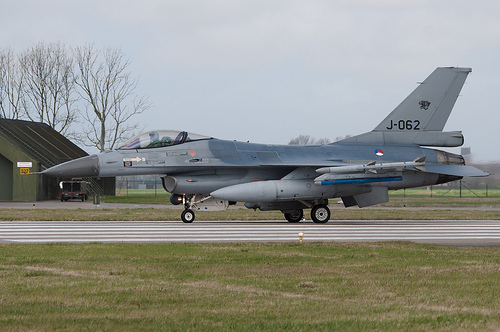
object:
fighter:
[28, 66, 491, 221]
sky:
[2, 4, 494, 176]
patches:
[3, 240, 494, 325]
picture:
[1, 0, 498, 327]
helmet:
[147, 131, 160, 142]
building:
[0, 119, 116, 202]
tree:
[3, 62, 25, 113]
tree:
[41, 46, 67, 122]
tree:
[79, 53, 111, 139]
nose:
[35, 161, 97, 178]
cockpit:
[126, 126, 197, 148]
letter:
[387, 119, 394, 130]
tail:
[375, 63, 472, 150]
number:
[398, 119, 406, 131]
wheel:
[310, 204, 331, 223]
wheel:
[179, 209, 199, 224]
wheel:
[284, 208, 304, 223]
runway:
[2, 221, 495, 238]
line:
[62, 227, 71, 229]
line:
[124, 232, 139, 237]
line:
[163, 228, 169, 229]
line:
[104, 219, 108, 222]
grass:
[51, 211, 173, 219]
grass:
[383, 209, 493, 221]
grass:
[23, 252, 499, 314]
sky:
[146, 9, 443, 64]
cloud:
[355, 27, 433, 56]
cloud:
[94, 11, 153, 33]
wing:
[433, 163, 488, 176]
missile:
[315, 161, 435, 172]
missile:
[207, 179, 380, 202]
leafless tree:
[77, 43, 116, 153]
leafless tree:
[24, 35, 64, 138]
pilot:
[145, 126, 162, 150]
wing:
[159, 148, 474, 190]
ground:
[35, 256, 497, 301]